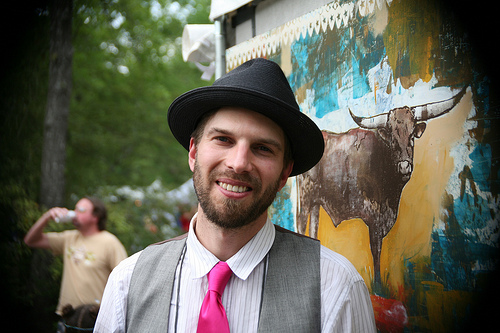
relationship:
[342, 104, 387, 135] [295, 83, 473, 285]
horn on a bull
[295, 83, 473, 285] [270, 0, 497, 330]
bull on a painting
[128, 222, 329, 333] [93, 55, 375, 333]
gray vest on a man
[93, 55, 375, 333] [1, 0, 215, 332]
man in background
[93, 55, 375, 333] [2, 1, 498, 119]
man on background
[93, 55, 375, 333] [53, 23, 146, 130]
man on background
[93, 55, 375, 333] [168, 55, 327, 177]
man wearing hat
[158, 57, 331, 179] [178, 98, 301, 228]
hat on head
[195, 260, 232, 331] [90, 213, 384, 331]
tie on shirt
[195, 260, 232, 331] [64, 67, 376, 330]
tie on man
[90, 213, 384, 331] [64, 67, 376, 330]
shirt on man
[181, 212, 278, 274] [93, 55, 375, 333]
collar on man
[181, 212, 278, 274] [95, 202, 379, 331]
collar on shirt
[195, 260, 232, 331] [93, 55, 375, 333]
tie on man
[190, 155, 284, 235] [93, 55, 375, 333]
beard on man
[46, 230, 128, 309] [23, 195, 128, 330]
shirt on background person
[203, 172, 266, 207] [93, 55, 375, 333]
smile on man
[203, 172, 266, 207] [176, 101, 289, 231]
smile on face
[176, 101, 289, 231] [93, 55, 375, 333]
face on man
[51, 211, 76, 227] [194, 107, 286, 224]
can held up to face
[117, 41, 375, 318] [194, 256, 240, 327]
man wearing tie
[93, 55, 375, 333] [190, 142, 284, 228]
man has beard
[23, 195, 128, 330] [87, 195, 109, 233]
background person has hair